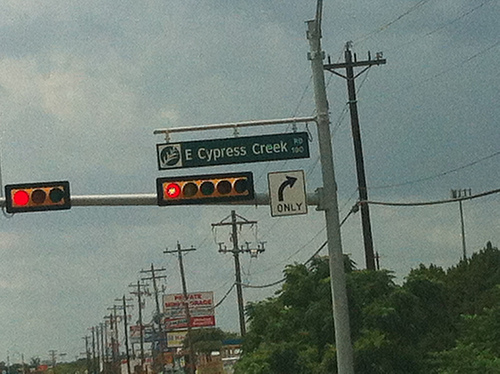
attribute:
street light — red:
[154, 170, 255, 210]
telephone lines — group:
[364, 9, 453, 222]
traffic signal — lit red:
[4, 179, 73, 214]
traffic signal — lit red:
[153, 170, 254, 206]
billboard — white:
[161, 290, 217, 329]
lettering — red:
[162, 292, 211, 305]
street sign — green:
[155, 129, 311, 171]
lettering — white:
[182, 135, 305, 161]